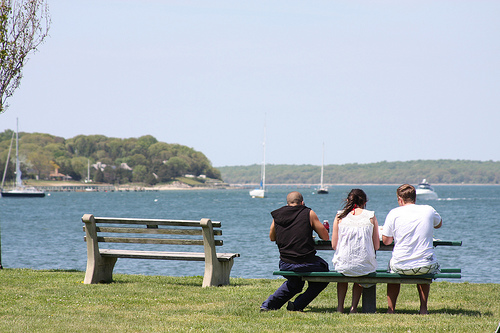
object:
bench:
[80, 211, 241, 289]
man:
[257, 191, 330, 311]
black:
[270, 205, 318, 263]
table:
[269, 232, 464, 314]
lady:
[326, 187, 381, 315]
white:
[343, 229, 363, 256]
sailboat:
[248, 148, 266, 199]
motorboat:
[406, 173, 440, 201]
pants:
[263, 259, 327, 309]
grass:
[0, 268, 499, 333]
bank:
[1, 268, 499, 332]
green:
[449, 241, 460, 248]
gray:
[212, 268, 225, 279]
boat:
[3, 115, 47, 199]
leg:
[257, 270, 304, 313]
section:
[139, 162, 169, 187]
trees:
[90, 162, 104, 183]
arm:
[330, 214, 342, 250]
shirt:
[332, 207, 377, 278]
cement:
[203, 263, 211, 276]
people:
[380, 182, 448, 316]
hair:
[335, 187, 367, 221]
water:
[0, 178, 499, 280]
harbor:
[0, 182, 482, 197]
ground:
[0, 267, 499, 332]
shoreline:
[111, 180, 227, 192]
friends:
[328, 182, 444, 316]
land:
[0, 128, 236, 191]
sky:
[0, 1, 499, 170]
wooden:
[162, 228, 192, 235]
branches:
[30, 30, 46, 52]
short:
[156, 281, 181, 300]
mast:
[9, 118, 24, 188]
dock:
[32, 180, 208, 194]